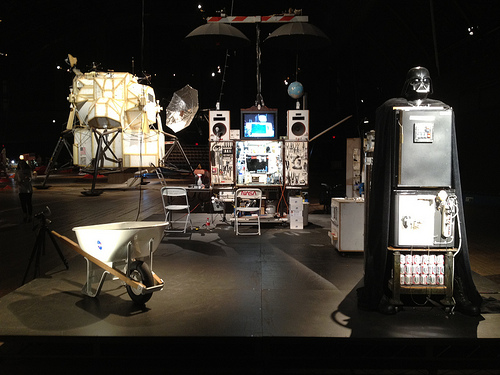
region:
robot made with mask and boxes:
[371, 51, 472, 324]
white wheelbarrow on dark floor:
[41, 206, 196, 312]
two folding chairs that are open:
[150, 180, 295, 250]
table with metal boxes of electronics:
[180, 95, 310, 190]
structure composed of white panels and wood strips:
[65, 60, 161, 175]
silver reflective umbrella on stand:
[155, 71, 200, 146]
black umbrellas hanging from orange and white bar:
[185, 5, 320, 56]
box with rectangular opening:
[227, 130, 282, 186]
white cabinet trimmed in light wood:
[321, 186, 366, 253]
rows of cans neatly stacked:
[383, 246, 453, 291]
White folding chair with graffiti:
[232, 185, 264, 237]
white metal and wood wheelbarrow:
[46, 217, 168, 309]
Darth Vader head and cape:
[381, 62, 453, 110]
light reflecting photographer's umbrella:
[163, 84, 199, 132]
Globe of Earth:
[285, 76, 307, 111]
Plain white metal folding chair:
[159, 186, 194, 233]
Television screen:
[237, 106, 280, 139]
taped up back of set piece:
[76, 81, 163, 169]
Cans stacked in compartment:
[395, 251, 452, 288]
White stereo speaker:
[286, 109, 309, 139]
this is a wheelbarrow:
[57, 223, 172, 297]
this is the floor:
[181, 251, 285, 321]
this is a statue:
[406, 59, 429, 99]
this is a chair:
[233, 188, 263, 231]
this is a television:
[240, 110, 276, 142]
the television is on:
[242, 111, 274, 132]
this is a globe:
[286, 79, 300, 98]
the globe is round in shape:
[288, 83, 305, 97]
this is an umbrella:
[183, 22, 244, 44]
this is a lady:
[11, 159, 33, 214]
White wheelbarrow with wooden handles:
[43, 212, 168, 299]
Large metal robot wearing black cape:
[362, 33, 480, 339]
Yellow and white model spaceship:
[67, 61, 166, 180]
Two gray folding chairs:
[153, 175, 275, 247]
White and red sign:
[201, 9, 314, 26]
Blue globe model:
[272, 77, 311, 104]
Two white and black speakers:
[199, 104, 316, 142]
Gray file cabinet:
[324, 192, 365, 259]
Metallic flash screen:
[157, 86, 204, 136]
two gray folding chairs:
[152, 179, 269, 244]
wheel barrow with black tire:
[57, 217, 174, 308]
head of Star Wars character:
[382, 62, 449, 129]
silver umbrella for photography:
[162, 83, 200, 133]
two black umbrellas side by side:
[190, 14, 332, 61]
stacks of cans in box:
[393, 253, 447, 290]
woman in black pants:
[9, 147, 40, 230]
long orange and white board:
[194, 10, 316, 32]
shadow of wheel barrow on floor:
[35, 284, 145, 326]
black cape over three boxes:
[357, 115, 396, 303]